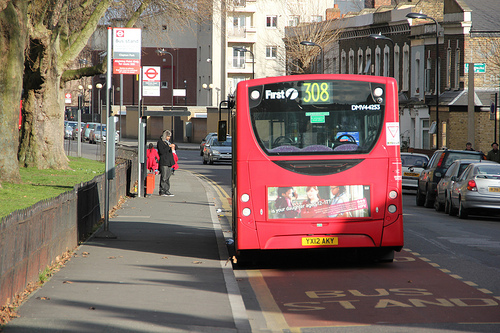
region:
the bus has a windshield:
[257, 97, 381, 159]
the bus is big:
[222, 74, 419, 274]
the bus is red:
[229, 69, 408, 264]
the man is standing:
[155, 121, 176, 198]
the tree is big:
[28, 49, 66, 158]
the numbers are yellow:
[301, 81, 334, 109]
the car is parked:
[448, 158, 493, 228]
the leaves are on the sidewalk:
[10, 256, 70, 321]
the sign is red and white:
[143, 61, 164, 98]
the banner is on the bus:
[261, 181, 376, 228]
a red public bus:
[206, 64, 418, 301]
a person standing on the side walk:
[148, 115, 195, 203]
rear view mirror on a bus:
[212, 90, 232, 140]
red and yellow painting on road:
[250, 261, 489, 331]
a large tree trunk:
[19, 39, 80, 172]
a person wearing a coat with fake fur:
[153, 125, 180, 186]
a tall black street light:
[412, 5, 447, 152]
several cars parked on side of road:
[61, 111, 128, 151]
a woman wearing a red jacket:
[146, 131, 158, 174]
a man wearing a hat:
[490, 137, 498, 159]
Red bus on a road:
[220, 68, 411, 255]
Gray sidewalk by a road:
[109, 211, 226, 327]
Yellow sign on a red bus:
[276, 226, 383, 255]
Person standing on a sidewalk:
[149, 128, 193, 199]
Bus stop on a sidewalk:
[89, 18, 174, 231]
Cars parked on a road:
[416, 133, 499, 203]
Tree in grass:
[2, 23, 118, 220]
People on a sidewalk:
[138, 128, 191, 193]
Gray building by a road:
[181, 5, 318, 122]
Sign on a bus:
[283, 73, 338, 108]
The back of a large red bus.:
[232, 70, 405, 272]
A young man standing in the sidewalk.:
[154, 127, 178, 197]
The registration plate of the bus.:
[300, 235, 339, 247]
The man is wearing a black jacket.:
[155, 137, 176, 168]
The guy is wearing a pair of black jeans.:
[157, 162, 171, 195]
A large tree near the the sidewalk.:
[20, 0, 113, 170]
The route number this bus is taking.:
[300, 82, 335, 105]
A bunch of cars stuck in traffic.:
[402, 144, 499, 220]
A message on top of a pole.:
[100, 25, 141, 234]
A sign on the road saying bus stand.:
[279, 283, 499, 315]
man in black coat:
[152, 129, 178, 197]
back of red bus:
[227, 70, 405, 267]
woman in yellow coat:
[144, 140, 159, 173]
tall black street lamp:
[403, 9, 441, 166]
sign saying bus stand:
[283, 280, 498, 315]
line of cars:
[61, 119, 120, 144]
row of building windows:
[297, 35, 468, 97]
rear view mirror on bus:
[216, 114, 227, 144]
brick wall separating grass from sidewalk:
[0, 154, 137, 320]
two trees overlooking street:
[0, 0, 77, 187]